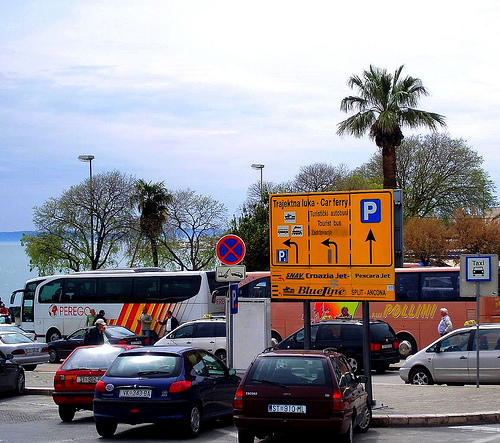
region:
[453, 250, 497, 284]
A taxi sign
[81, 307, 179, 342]
People talking outside of a bus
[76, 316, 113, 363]
Man walking near road.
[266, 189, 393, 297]
A yellow sign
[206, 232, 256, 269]
A blue circular sign with a red X.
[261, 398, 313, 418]
European license plate.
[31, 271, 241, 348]
Large white Perego bus.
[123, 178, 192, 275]
A palm tree near the road.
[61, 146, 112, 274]
Light pole near the road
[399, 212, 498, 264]
Fluffy orange trees.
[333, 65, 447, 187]
palm tree with green leaves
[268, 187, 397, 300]
yellow traffic sign with arrows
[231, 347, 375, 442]
maroon colored four door car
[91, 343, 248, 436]
blue colored two door car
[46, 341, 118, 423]
red colored compact car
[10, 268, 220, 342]
white colored long bus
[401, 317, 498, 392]
grey colored minivan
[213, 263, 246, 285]
tow away zone traffic sign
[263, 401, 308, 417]
white license plate on rear of car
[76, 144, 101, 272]
street lamp post on road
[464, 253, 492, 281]
taxi sign with blue trim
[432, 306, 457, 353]
man with a big belly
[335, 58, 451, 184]
palm tree and cloudy sky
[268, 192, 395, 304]
orange street direction sign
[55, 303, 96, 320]
the word perego in red letters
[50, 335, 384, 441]
three cars parked diagonally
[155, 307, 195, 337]
man in dark jacket and white shirt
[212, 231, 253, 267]
blue and red sign X sign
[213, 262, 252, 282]
sign showing car being towed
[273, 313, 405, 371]
man leaning on dark mini van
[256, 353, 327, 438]
a car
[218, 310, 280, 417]
a car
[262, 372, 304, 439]
a car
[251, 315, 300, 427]
a car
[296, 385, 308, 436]
a car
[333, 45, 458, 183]
A palm tree with fronds on it.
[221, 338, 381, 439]
A red car in a parking lot.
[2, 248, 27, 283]
The ocean is blue.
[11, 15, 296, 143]
The sky is cloudy.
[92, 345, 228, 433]
A blue car in the parking lot.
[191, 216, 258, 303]
A sign with a towing car graphic.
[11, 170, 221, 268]
Trees next to a palm tree.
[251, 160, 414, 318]
The road sign is yellow.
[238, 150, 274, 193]
A pole with a light on it.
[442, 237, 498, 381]
A sign for taxis.